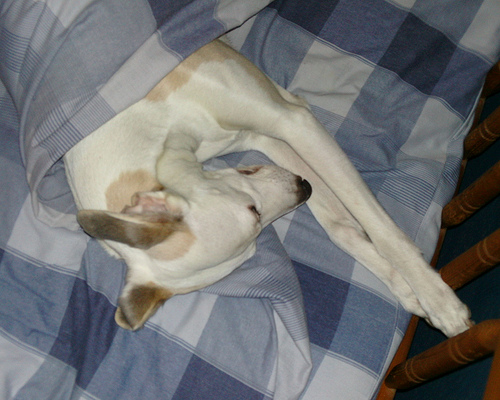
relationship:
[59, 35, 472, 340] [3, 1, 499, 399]
dog on bed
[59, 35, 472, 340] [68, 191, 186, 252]
dog has ear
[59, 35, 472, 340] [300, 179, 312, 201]
dog has nose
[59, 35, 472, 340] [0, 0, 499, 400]
dog wrapped in sheet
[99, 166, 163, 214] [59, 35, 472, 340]
spot on dog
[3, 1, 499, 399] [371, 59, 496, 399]
bed has headboard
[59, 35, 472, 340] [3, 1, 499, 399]
dog lying on bed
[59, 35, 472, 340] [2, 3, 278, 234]
dog under sheet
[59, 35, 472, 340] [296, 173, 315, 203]
dog has nose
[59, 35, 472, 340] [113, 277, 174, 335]
dog has ear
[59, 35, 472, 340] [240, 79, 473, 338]
dog has front leg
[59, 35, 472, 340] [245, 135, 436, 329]
dog has front leg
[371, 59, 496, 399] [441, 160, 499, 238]
headboard has rung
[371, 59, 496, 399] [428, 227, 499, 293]
headboard has rung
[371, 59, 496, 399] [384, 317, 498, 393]
headboard has rung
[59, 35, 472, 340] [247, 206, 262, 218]
dog has left eye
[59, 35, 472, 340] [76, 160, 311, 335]
dog has head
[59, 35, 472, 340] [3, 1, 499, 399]
dog laying in bed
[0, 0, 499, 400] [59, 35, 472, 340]
sheet are under dog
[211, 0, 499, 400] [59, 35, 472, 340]
sheet under dog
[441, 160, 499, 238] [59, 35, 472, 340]
rung next to dog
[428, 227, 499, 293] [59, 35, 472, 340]
rung next to dog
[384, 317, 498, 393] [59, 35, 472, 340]
rung next to dog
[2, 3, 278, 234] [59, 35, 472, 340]
sheet covering dog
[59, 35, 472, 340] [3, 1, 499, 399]
dog laying down on bed